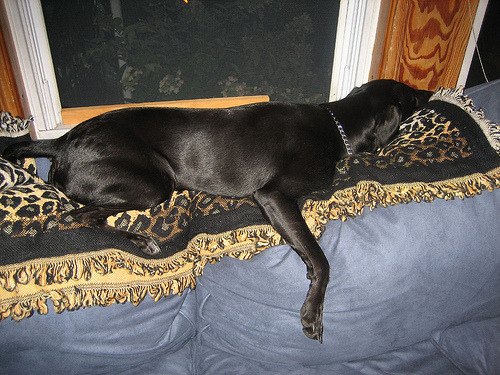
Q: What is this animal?
A: Dog.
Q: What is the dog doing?
A: Sleeping.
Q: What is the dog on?
A: Blanket.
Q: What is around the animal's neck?
A: Collar.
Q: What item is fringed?
A: The blanket.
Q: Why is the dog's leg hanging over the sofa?
A: The Dog is resting.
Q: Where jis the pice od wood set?
A: In the window sill.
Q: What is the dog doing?
A: Sleeping.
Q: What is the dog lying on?
A: A cheetah print blanket.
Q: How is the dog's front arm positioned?
A: On the side of the couch.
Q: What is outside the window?
A: Plants.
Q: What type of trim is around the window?
A: White trim.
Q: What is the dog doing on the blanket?
A: Sleeping.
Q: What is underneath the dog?
A: A blanket.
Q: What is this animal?
A: Dog.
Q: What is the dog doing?
A: Sleeping.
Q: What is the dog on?
A: Blanket.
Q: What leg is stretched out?
A: Front right of the dog.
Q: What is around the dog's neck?
A: Collar.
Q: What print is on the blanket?
A: Cheetah print.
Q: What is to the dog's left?
A: Window.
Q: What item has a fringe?
A: The blanket.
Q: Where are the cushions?
A: Under the blanket.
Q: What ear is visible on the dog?
A: The right one.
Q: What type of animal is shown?
A: Dog.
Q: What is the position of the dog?
A: Laying.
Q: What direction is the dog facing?
A: Right.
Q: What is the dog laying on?
A: Blanket.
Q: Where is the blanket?
A: Back of the couch.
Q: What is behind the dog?
A: Window.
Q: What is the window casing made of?
A: Wood.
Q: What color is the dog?
A: Black.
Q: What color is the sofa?
A: Blue.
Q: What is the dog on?
A: The rug.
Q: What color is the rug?
A: Black and gold.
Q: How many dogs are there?
A: One.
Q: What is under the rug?
A: The sofa.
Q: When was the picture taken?
A: At night.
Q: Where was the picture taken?
A: On the back of sofa.